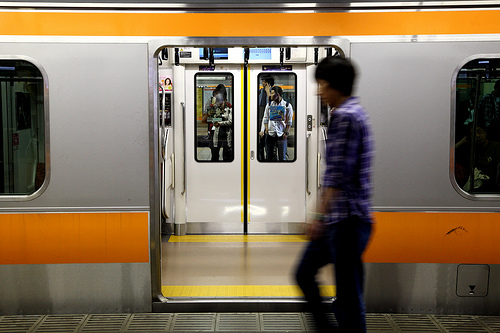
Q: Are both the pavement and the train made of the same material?
A: Yes, both the pavement and the train are made of metal.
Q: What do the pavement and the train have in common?
A: The material, both the pavement and the train are metallic.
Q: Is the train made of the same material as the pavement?
A: Yes, both the train and the pavement are made of metal.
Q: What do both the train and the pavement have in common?
A: The material, both the train and the pavement are metallic.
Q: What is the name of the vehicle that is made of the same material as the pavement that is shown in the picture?
A: The vehicle is a train.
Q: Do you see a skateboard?
A: No, there are no skateboards.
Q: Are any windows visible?
A: Yes, there is a window.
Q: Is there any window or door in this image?
A: Yes, there is a window.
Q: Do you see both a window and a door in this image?
A: Yes, there are both a window and a door.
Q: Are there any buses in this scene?
A: No, there are no buses.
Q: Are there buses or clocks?
A: No, there are no buses or clocks.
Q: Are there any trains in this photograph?
A: Yes, there is a train.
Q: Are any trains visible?
A: Yes, there is a train.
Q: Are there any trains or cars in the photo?
A: Yes, there is a train.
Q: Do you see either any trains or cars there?
A: Yes, there is a train.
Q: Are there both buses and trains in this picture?
A: No, there is a train but no buses.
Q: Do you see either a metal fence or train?
A: Yes, there is a metal train.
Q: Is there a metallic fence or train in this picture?
A: Yes, there is a metal train.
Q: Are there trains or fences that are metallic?
A: Yes, the train is metallic.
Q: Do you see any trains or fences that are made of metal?
A: Yes, the train is made of metal.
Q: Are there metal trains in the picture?
A: Yes, there is a metal train.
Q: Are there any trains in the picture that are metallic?
A: Yes, there is a train that is metallic.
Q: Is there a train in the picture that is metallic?
A: Yes, there is a train that is metallic.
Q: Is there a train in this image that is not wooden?
A: Yes, there is a metallic train.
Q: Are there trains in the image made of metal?
A: Yes, there is a train that is made of metal.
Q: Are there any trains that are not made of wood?
A: Yes, there is a train that is made of metal.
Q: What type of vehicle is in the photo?
A: The vehicle is a train.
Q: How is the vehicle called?
A: The vehicle is a train.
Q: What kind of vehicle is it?
A: The vehicle is a train.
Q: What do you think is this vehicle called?
A: This is a train.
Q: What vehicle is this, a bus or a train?
A: This is a train.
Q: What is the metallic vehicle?
A: The vehicle is a train.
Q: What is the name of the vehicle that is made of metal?
A: The vehicle is a train.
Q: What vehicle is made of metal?
A: The vehicle is a train.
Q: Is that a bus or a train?
A: That is a train.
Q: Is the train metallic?
A: Yes, the train is metallic.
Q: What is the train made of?
A: The train is made of metal.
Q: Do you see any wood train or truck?
A: No, there is a train but it is metallic.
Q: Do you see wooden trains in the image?
A: No, there is a train but it is metallic.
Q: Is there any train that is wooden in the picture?
A: No, there is a train but it is metallic.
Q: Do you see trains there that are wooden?
A: No, there is a train but it is metallic.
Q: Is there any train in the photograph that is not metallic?
A: No, there is a train but it is metallic.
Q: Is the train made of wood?
A: No, the train is made of metal.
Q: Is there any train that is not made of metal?
A: No, there is a train but it is made of metal.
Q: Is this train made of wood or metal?
A: The train is made of metal.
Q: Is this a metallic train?
A: Yes, this is a metallic train.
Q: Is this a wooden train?
A: No, this is a metallic train.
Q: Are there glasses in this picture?
A: No, there are no glasses.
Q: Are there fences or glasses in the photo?
A: No, there are no glasses or fences.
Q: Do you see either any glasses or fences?
A: No, there are no glasses or fences.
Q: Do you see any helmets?
A: No, there are no helmets.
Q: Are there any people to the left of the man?
A: Yes, there is a person to the left of the man.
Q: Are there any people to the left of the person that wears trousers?
A: Yes, there is a person to the left of the man.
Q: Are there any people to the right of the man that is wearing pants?
A: No, the person is to the left of the man.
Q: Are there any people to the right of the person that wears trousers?
A: No, the person is to the left of the man.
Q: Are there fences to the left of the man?
A: No, there is a person to the left of the man.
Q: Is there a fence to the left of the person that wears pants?
A: No, there is a person to the left of the man.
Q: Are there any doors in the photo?
A: Yes, there is a door.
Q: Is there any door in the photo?
A: Yes, there is a door.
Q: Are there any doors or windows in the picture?
A: Yes, there is a door.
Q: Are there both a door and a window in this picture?
A: Yes, there are both a door and a window.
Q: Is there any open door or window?
A: Yes, there is an open door.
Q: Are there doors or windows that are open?
A: Yes, the door is open.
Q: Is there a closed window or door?
A: Yes, there is a closed door.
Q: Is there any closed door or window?
A: Yes, there is a closed door.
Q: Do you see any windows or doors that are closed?
A: Yes, the door is closed.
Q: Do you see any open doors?
A: Yes, there is an open door.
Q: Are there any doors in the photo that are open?
A: Yes, there is a door that is open.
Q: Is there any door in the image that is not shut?
A: Yes, there is a open door.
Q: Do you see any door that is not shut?
A: Yes, there is a open door.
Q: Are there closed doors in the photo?
A: Yes, there is a closed door.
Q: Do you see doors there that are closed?
A: Yes, there is a door that is closed.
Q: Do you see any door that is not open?
A: Yes, there is an closed door.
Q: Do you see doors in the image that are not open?
A: Yes, there is an closed door.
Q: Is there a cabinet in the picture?
A: No, there are no cabinets.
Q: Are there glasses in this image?
A: No, there are no glasses.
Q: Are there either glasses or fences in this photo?
A: No, there are no glasses or fences.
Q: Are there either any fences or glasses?
A: No, there are no glasses or fences.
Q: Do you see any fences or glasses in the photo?
A: No, there are no glasses or fences.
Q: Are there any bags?
A: No, there are no bags.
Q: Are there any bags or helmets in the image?
A: No, there are no bags or helmets.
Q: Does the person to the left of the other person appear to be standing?
A: Yes, the person is standing.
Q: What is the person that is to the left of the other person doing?
A: The person is standing.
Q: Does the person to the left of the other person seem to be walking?
A: No, the person is standing.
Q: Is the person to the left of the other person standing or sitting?
A: The person is standing.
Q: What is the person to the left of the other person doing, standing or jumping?
A: The person is standing.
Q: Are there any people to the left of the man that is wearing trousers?
A: Yes, there is a person to the left of the man.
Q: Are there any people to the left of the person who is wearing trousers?
A: Yes, there is a person to the left of the man.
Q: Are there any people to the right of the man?
A: No, the person is to the left of the man.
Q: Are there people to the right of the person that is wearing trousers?
A: No, the person is to the left of the man.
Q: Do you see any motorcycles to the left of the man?
A: No, there is a person to the left of the man.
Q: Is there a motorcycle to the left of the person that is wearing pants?
A: No, there is a person to the left of the man.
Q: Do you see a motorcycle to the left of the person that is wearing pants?
A: No, there is a person to the left of the man.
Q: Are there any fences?
A: No, there are no fences.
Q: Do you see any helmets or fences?
A: No, there are no fences or helmets.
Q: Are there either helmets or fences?
A: No, there are no fences or helmets.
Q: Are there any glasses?
A: No, there are no glasses.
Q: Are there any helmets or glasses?
A: No, there are no glasses or helmets.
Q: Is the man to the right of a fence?
A: No, the man is to the right of a person.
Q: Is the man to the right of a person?
A: Yes, the man is to the right of a person.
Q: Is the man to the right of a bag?
A: No, the man is to the right of a person.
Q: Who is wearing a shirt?
A: The man is wearing a shirt.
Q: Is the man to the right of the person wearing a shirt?
A: Yes, the man is wearing a shirt.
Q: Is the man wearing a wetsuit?
A: No, the man is wearing a shirt.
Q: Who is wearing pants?
A: The man is wearing pants.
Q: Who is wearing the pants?
A: The man is wearing pants.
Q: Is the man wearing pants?
A: Yes, the man is wearing pants.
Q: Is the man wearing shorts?
A: No, the man is wearing pants.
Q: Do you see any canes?
A: No, there are no canes.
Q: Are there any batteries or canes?
A: No, there are no canes or batteries.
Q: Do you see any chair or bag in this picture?
A: No, there are no bags or chairs.